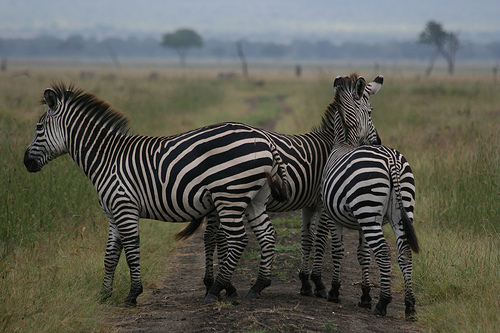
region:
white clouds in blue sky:
[14, 8, 90, 38]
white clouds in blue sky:
[114, 7, 171, 44]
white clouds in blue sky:
[206, 7, 256, 35]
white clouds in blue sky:
[250, 22, 325, 72]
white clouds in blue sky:
[313, 5, 369, 48]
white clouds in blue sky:
[440, 15, 490, 55]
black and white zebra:
[20, 80, 283, 301]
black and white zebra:
[321, 60, 428, 307]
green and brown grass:
[30, 188, 73, 235]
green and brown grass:
[152, 251, 202, 305]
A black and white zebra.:
[22, 76, 290, 310]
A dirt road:
[110, 92, 427, 331]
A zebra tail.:
[387, 157, 420, 254]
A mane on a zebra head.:
[36, 77, 131, 137]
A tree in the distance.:
[158, 27, 203, 68]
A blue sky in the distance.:
[0, 0, 497, 42]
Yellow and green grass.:
[0, 60, 498, 331]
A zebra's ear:
[40, 89, 59, 111]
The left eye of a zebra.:
[34, 122, 44, 129]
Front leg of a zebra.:
[111, 195, 144, 310]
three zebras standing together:
[26, 45, 458, 302]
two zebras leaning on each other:
[251, 55, 422, 303]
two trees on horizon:
[149, 25, 464, 75]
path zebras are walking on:
[161, 116, 403, 331]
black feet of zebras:
[93, 273, 413, 318]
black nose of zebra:
[21, 146, 40, 178]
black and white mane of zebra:
[42, 76, 133, 125]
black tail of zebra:
[400, 216, 423, 248]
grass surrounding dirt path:
[5, 71, 489, 315]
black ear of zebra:
[37, 88, 57, 108]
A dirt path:
[134, 94, 411, 331]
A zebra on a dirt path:
[319, 74, 422, 316]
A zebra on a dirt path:
[23, 83, 292, 307]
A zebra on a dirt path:
[175, 73, 384, 300]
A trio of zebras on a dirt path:
[23, 74, 422, 319]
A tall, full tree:
[163, 28, 203, 68]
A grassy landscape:
[4, 58, 498, 332]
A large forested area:
[7, 33, 499, 62]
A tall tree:
[415, 20, 460, 72]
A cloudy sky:
[6, 0, 499, 29]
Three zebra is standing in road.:
[53, 88, 426, 258]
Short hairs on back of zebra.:
[67, 85, 131, 141]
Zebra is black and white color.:
[36, 114, 280, 227]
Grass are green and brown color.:
[416, 130, 489, 276]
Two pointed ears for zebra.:
[333, 68, 399, 100]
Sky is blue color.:
[215, 5, 402, 32]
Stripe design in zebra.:
[102, 143, 255, 190]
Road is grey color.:
[166, 253, 334, 330]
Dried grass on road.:
[142, 278, 342, 331]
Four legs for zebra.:
[75, 206, 292, 313]